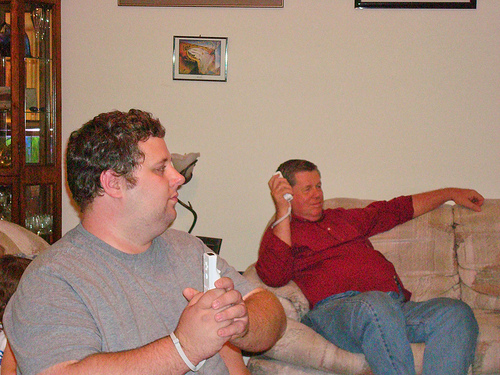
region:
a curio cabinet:
[0, 3, 64, 239]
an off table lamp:
[165, 149, 197, 234]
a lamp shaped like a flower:
[169, 150, 199, 232]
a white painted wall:
[59, 0, 499, 278]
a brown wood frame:
[114, 0, 283, 6]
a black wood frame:
[352, 0, 476, 10]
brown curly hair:
[66, 107, 164, 217]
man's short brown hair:
[275, 157, 318, 185]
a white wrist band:
[168, 328, 204, 369]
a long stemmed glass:
[30, 1, 47, 55]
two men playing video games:
[23, 95, 477, 367]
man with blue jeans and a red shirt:
[247, 148, 485, 373]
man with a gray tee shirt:
[0, 103, 290, 370]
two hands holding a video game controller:
[169, 243, 253, 356]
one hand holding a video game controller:
[260, 168, 300, 235]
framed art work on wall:
[160, 28, 237, 87]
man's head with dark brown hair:
[54, 100, 194, 248]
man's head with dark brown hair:
[265, 148, 333, 225]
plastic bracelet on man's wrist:
[160, 329, 201, 373]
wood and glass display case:
[0, 26, 69, 232]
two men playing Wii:
[11, 92, 480, 374]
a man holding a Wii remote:
[252, 142, 344, 273]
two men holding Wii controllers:
[48, 83, 340, 335]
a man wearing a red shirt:
[239, 145, 405, 299]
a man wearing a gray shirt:
[26, 106, 238, 361]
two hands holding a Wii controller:
[171, 240, 247, 352]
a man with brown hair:
[45, 104, 195, 233]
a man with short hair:
[261, 152, 336, 219]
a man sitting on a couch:
[236, 162, 485, 361]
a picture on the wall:
[162, 28, 239, 90]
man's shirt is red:
[240, 191, 415, 301]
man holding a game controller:
[255, 160, 490, 371]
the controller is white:
[260, 156, 305, 221]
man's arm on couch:
[331, 176, 498, 233]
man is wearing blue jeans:
[295, 271, 490, 373]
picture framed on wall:
[163, 21, 254, 101]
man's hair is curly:
[55, 99, 170, 202]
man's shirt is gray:
[10, 209, 289, 371]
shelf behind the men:
[2, 4, 80, 265]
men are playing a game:
[0, 43, 491, 373]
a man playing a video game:
[259, 158, 483, 368]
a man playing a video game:
[4, 110, 285, 370]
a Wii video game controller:
[199, 252, 221, 295]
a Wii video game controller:
[270, 170, 294, 202]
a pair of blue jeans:
[304, 293, 475, 373]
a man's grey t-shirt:
[4, 220, 262, 373]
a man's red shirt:
[255, 195, 415, 306]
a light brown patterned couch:
[238, 198, 498, 373]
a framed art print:
[169, 34, 227, 82]